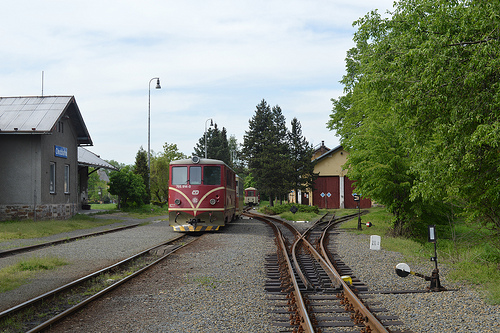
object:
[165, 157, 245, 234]
train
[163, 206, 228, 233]
plow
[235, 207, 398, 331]
train track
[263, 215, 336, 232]
apart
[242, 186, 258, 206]
train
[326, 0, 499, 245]
trees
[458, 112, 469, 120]
leaves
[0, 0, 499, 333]
summer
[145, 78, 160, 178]
street light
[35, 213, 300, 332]
gravel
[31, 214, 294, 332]
ground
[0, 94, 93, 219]
building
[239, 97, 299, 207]
pine trees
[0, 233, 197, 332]
tracks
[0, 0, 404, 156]
clouds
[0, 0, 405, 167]
sky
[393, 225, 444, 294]
junction box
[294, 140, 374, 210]
building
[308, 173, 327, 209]
doors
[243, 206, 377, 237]
three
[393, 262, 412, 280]
signal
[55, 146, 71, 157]
sign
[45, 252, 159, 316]
grass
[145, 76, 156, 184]
lamp post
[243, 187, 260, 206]
train car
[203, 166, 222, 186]
window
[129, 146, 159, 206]
trees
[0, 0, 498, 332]
background